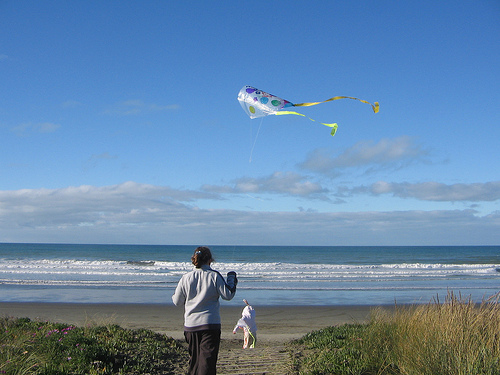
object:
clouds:
[3, 177, 151, 225]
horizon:
[2, 0, 499, 246]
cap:
[1, 257, 500, 279]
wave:
[1, 259, 84, 286]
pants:
[183, 328, 222, 373]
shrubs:
[371, 307, 422, 337]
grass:
[347, 349, 393, 373]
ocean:
[245, 244, 496, 287]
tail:
[274, 111, 338, 137]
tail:
[294, 96, 379, 114]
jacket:
[171, 265, 237, 331]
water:
[335, 248, 413, 265]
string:
[249, 117, 264, 163]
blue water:
[220, 247, 500, 263]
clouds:
[184, 206, 286, 238]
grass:
[2, 311, 78, 346]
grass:
[440, 339, 496, 373]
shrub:
[69, 327, 135, 347]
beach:
[0, 300, 378, 340]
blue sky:
[0, 4, 497, 84]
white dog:
[233, 299, 257, 349]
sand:
[237, 346, 265, 363]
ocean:
[0, 243, 140, 299]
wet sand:
[0, 301, 500, 320]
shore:
[259, 313, 322, 339]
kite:
[236, 84, 379, 136]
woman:
[171, 246, 239, 374]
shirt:
[171, 266, 240, 331]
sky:
[3, 6, 500, 244]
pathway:
[219, 348, 283, 374]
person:
[233, 299, 258, 349]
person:
[169, 246, 238, 373]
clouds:
[362, 176, 500, 208]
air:
[161, 50, 435, 131]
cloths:
[237, 305, 258, 332]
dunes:
[256, 311, 320, 329]